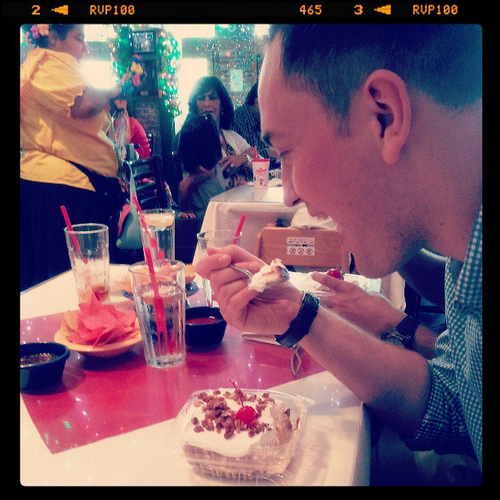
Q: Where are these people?
A: Restaurant.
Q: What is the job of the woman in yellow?
A: Waitress.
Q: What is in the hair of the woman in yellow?
A: Flowers.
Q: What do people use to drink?
A: Red straws.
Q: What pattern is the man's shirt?
A: Checked.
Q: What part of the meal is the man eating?
A: Dessert.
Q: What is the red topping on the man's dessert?
A: Cherry.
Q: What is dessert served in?
A: Plastic container.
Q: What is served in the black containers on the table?
A: Dip for the chips.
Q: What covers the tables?
A: White and red table cloths.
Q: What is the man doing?
A: Eating cake.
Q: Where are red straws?
A: In glasses.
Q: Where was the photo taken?
A: In a restaurant.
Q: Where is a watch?
A: Around man's wrist.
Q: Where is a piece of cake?
A: On a fork.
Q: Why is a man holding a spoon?
A: To eat.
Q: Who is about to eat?
A: A man.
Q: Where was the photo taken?
A: In a restaurant.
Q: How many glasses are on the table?
A: Four.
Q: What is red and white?
A: The table.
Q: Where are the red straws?
A: In glasses.